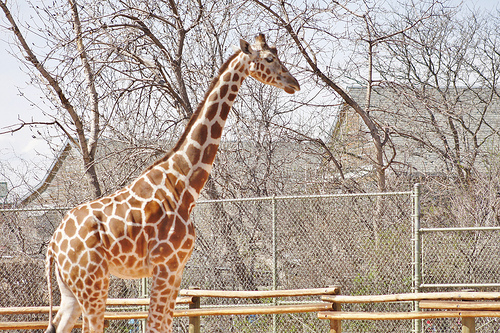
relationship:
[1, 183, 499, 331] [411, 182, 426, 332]
fence with poles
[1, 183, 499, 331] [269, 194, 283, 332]
fence with poles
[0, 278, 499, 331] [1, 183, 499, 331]
bleachers near fence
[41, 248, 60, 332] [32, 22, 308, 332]
tail on giraffe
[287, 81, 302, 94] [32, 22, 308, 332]
mouth on giraffe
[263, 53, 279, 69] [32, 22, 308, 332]
eye on giraffe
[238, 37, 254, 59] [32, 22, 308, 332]
ears of giraffe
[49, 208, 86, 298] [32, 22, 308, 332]
hind of giraffe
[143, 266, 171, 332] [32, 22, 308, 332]
legs of giraffe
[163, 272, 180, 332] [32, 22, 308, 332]
legs of giraffe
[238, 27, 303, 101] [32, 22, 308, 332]
head of giraffe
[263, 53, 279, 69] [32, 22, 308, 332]
eye of giraffe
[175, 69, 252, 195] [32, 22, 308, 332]
neck of giraffe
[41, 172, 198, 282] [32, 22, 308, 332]
body of giraffe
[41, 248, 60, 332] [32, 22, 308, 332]
tail of giraffe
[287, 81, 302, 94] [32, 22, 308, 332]
mouth of giraffe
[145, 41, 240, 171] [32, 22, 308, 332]
hair of giraffe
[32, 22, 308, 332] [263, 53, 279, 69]
giraffe has eye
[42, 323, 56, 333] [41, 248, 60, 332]
ball on tail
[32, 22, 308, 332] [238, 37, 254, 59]
giraffe has ears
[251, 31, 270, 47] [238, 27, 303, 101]
horn on head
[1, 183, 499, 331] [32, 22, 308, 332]
fence behind giraffe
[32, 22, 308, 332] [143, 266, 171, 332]
giraffe has legs